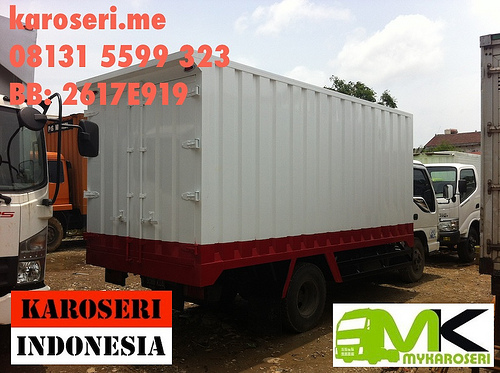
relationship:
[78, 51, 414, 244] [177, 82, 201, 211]
storage box has latches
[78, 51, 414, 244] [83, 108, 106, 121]
storage box has hinges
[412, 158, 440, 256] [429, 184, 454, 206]
truck has mirror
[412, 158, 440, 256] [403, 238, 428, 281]
truck has wheels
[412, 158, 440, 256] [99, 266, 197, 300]
truck has mud flaps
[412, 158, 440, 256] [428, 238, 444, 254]
truck has bumper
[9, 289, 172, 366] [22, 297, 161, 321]
logo has letters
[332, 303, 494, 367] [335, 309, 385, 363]
logo has design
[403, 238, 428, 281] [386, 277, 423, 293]
wheels are in shadow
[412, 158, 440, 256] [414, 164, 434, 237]
truck has door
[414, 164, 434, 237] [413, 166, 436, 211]
door has window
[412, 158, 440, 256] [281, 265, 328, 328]
truck has tire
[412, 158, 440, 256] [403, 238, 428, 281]
truck has tire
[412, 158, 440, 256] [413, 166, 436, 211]
truck has window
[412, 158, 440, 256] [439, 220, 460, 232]
truck has light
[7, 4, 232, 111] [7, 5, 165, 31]
ad has letters